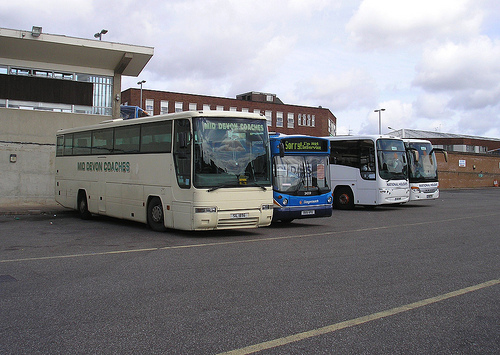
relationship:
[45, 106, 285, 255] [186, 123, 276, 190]
bus has window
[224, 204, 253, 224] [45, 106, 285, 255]
licence plate on bus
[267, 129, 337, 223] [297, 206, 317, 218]
bus has license plate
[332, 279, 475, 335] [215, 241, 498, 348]
line on road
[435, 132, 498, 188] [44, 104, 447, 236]
building beside buses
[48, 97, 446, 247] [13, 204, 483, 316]
buses in parking lot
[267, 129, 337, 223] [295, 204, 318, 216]
bus has licence plate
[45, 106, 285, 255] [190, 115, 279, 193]
bus has windshield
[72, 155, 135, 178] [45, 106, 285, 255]
name on bus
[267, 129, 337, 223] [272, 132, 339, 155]
bus has digital window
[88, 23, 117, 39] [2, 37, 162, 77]
lights on roof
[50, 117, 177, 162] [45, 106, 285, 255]
window on bus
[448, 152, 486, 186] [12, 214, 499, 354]
wall in parking lot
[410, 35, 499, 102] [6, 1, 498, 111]
clouds in sky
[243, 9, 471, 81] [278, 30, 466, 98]
clouds are in sky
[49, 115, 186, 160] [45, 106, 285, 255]
windows are attached to bus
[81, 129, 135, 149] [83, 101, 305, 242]
window on vehicle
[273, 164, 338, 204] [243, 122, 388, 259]
window on vehicle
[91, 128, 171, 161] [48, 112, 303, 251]
window on bus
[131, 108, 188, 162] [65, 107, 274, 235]
window on bus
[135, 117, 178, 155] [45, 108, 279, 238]
window on vehicle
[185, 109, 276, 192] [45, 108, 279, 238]
window on vehicle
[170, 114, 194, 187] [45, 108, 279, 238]
window on vehicle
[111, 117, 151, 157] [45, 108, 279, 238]
window on vehicle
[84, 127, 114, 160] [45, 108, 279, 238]
window on vehicle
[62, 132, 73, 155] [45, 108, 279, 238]
window built into vehicle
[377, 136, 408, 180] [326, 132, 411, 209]
window built into vehicle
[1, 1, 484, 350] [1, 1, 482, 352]
scene taking place during daytime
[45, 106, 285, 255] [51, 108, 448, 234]
bus standing in row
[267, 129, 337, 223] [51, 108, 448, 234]
bus standing in row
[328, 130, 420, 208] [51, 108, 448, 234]
bus standing in row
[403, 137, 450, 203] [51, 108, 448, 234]
bus standing in row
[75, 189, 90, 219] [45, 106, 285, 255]
tire mounted on bus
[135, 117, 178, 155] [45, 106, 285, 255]
window built into bus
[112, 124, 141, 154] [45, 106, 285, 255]
window built into bus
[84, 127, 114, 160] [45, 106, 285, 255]
window built into bus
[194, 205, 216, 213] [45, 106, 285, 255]
headlight built into bus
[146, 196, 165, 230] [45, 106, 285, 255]
tire mounted on bus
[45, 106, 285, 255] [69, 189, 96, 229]
bus has a tire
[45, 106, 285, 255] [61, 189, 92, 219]
bus has a tire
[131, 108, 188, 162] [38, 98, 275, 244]
window on bus